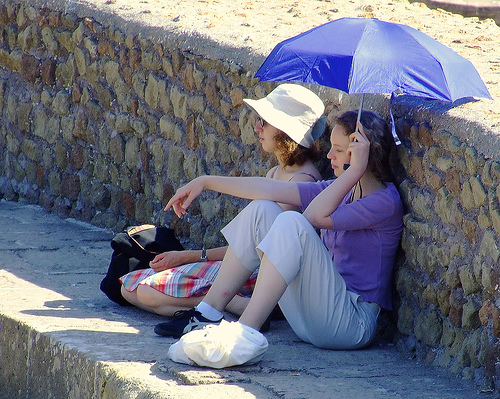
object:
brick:
[163, 147, 186, 180]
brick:
[456, 265, 485, 294]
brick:
[404, 213, 431, 242]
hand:
[163, 173, 211, 219]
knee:
[269, 210, 313, 246]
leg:
[235, 209, 347, 341]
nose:
[256, 120, 266, 130]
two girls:
[118, 82, 411, 369]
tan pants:
[218, 194, 382, 352]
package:
[168, 319, 270, 370]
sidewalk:
[0, 197, 481, 398]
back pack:
[99, 224, 186, 309]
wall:
[0, 0, 500, 396]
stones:
[105, 59, 123, 85]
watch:
[198, 248, 210, 262]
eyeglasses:
[262, 114, 272, 129]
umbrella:
[254, 16, 494, 173]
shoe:
[151, 307, 229, 339]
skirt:
[119, 258, 273, 299]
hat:
[241, 82, 327, 150]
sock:
[195, 300, 227, 323]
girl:
[151, 112, 424, 366]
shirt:
[296, 175, 404, 312]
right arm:
[210, 174, 335, 206]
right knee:
[235, 196, 282, 228]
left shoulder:
[371, 186, 405, 217]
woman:
[118, 82, 334, 333]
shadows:
[31, 327, 170, 396]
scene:
[1, 1, 499, 398]